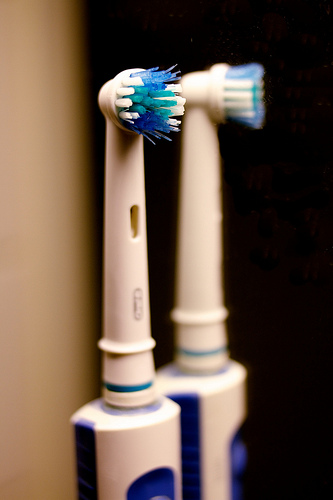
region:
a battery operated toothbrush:
[101, 326, 196, 438]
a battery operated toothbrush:
[119, 395, 200, 491]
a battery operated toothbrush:
[147, 430, 186, 495]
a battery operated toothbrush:
[123, 409, 176, 472]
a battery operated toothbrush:
[103, 420, 151, 475]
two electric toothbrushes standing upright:
[89, 59, 268, 497]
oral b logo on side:
[131, 284, 147, 328]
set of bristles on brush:
[112, 97, 132, 107]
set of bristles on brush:
[115, 87, 132, 94]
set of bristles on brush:
[114, 110, 137, 121]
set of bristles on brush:
[125, 78, 140, 86]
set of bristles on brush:
[218, 77, 248, 86]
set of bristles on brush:
[222, 91, 249, 98]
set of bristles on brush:
[222, 102, 248, 110]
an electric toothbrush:
[67, 65, 187, 497]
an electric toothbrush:
[158, 61, 265, 495]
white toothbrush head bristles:
[119, 76, 137, 124]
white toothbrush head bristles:
[165, 79, 183, 130]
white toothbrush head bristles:
[222, 80, 252, 115]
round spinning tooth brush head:
[103, 64, 185, 142]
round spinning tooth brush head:
[204, 61, 266, 128]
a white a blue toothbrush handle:
[69, 393, 184, 498]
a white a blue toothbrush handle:
[155, 356, 250, 495]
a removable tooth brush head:
[96, 64, 184, 408]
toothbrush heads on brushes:
[104, 57, 297, 322]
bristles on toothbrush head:
[109, 97, 132, 109]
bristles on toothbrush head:
[114, 86, 134, 94]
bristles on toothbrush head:
[122, 77, 143, 85]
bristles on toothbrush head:
[115, 112, 139, 125]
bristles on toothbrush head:
[225, 78, 253, 86]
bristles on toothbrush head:
[221, 93, 252, 98]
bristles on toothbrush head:
[221, 99, 251, 109]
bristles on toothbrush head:
[226, 110, 254, 114]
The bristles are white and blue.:
[103, 69, 202, 169]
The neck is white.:
[88, 121, 166, 414]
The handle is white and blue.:
[61, 398, 176, 499]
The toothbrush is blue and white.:
[62, 108, 188, 495]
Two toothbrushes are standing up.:
[76, 42, 289, 494]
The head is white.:
[176, 67, 283, 128]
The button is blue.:
[229, 436, 256, 475]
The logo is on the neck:
[123, 283, 153, 322]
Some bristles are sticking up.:
[108, 59, 199, 150]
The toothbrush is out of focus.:
[173, 56, 284, 494]